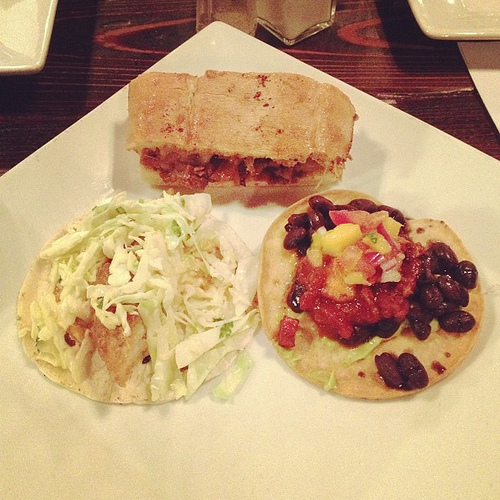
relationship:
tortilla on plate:
[49, 212, 225, 410] [54, 130, 476, 500]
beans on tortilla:
[310, 219, 455, 374] [267, 199, 479, 386]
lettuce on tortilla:
[116, 229, 191, 301] [49, 212, 225, 410]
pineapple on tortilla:
[328, 218, 359, 256] [267, 199, 479, 386]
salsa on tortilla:
[311, 288, 372, 329] [267, 199, 479, 386]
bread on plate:
[127, 77, 359, 182] [54, 130, 476, 500]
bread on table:
[127, 77, 359, 182] [73, 11, 130, 61]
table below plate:
[73, 11, 130, 61] [54, 130, 476, 500]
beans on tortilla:
[310, 219, 455, 374] [49, 212, 225, 410]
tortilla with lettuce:
[49, 212, 225, 410] [116, 229, 191, 301]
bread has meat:
[127, 77, 359, 182] [167, 147, 278, 187]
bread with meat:
[127, 77, 359, 182] [167, 147, 278, 187]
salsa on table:
[311, 288, 372, 329] [73, 11, 130, 61]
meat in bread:
[167, 147, 278, 187] [127, 77, 359, 182]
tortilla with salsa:
[267, 199, 479, 386] [311, 288, 372, 329]